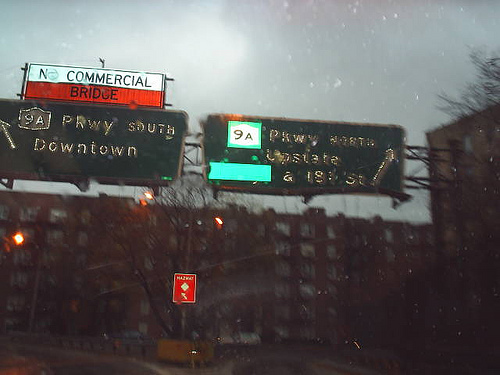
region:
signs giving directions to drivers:
[4, 48, 406, 218]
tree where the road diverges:
[96, 187, 261, 372]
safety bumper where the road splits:
[152, 336, 220, 365]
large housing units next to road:
[14, 192, 433, 346]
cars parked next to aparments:
[103, 327, 248, 345]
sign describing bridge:
[16, 64, 181, 104]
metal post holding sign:
[410, 135, 486, 360]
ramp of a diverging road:
[242, 335, 362, 374]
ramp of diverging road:
[7, 333, 145, 372]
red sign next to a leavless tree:
[170, 270, 202, 298]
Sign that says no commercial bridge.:
[28, 61, 173, 105]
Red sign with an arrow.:
[166, 269, 199, 306]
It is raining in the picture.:
[181, 25, 439, 102]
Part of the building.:
[43, 203, 468, 360]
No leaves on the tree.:
[124, 222, 237, 359]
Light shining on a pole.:
[6, 219, 51, 331]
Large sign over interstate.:
[6, 97, 189, 182]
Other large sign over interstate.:
[208, 105, 395, 211]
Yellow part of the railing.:
[138, 330, 223, 370]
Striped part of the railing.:
[353, 345, 410, 372]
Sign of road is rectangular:
[2, 91, 192, 199]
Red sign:
[166, 268, 203, 310]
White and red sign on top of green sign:
[14, 56, 170, 117]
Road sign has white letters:
[193, 107, 415, 207]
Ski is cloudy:
[4, 5, 498, 101]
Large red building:
[2, 194, 441, 371]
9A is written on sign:
[13, 101, 56, 139]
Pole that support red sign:
[176, 303, 191, 373]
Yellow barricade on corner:
[150, 334, 221, 365]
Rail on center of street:
[5, 321, 156, 356]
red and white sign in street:
[164, 265, 202, 312]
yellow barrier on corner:
[152, 327, 232, 370]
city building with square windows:
[274, 209, 343, 332]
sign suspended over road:
[195, 108, 417, 217]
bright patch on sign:
[226, 115, 262, 155]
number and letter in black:
[229, 121, 257, 149]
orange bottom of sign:
[17, 78, 174, 113]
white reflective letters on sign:
[31, 113, 181, 164]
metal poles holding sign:
[418, 135, 468, 203]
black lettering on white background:
[30, 62, 167, 94]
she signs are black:
[1, 87, 418, 204]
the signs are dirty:
[0, 93, 412, 212]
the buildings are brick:
[1, 86, 498, 373]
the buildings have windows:
[1, 95, 498, 372]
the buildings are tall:
[0, 97, 498, 374]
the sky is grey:
[0, 0, 499, 230]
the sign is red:
[168, 263, 197, 313]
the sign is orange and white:
[13, 62, 171, 122]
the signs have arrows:
[0, 112, 409, 215]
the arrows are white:
[0, 115, 398, 162]